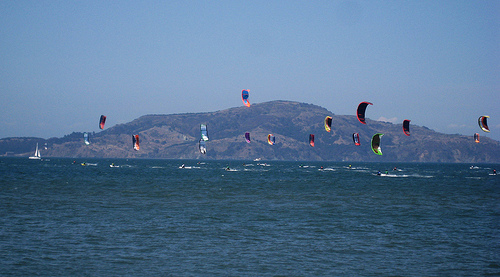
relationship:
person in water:
[70, 159, 80, 168] [4, 164, 497, 271]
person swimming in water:
[70, 159, 80, 168] [4, 164, 497, 271]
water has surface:
[4, 164, 497, 271] [2, 157, 498, 268]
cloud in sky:
[375, 114, 475, 136] [6, 10, 499, 143]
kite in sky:
[239, 87, 253, 114] [6, 10, 499, 143]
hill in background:
[10, 101, 500, 160] [7, 1, 499, 164]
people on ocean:
[65, 159, 498, 175] [4, 165, 500, 272]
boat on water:
[27, 144, 47, 166] [4, 164, 497, 271]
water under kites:
[4, 164, 497, 271] [41, 81, 491, 161]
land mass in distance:
[6, 100, 499, 163] [9, 1, 498, 161]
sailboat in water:
[28, 142, 44, 161] [4, 164, 497, 271]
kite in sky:
[267, 126, 278, 149] [6, 10, 499, 143]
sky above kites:
[6, 10, 499, 143] [41, 81, 491, 161]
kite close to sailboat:
[83, 130, 93, 149] [28, 142, 44, 161]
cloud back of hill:
[367, 107, 454, 136] [10, 101, 500, 160]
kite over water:
[369, 129, 387, 158] [4, 164, 497, 271]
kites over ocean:
[41, 81, 491, 161] [4, 165, 500, 277]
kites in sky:
[41, 81, 491, 161] [6, 10, 499, 143]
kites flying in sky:
[41, 81, 491, 161] [6, 10, 499, 143]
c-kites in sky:
[302, 86, 490, 166] [6, 10, 499, 143]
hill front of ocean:
[10, 101, 500, 160] [4, 165, 500, 277]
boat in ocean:
[27, 144, 47, 166] [4, 165, 500, 277]